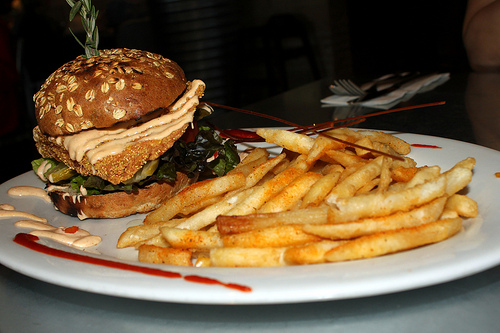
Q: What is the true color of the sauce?
A: Red.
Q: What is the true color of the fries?
A: Yellow.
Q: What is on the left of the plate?
A: A large burger.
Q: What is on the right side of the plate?
A: French fries.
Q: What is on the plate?
A: French fries and burger.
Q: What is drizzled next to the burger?
A: Mayonnaise.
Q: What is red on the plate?
A: Ketchup.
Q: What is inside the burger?
A: Meat.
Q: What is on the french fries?
A: Seasoning.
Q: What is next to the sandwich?
A: Fries.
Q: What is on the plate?
A: Food.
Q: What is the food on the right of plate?
A: Fries.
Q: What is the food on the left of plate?
A: Hamburger.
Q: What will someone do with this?
A: Eat it.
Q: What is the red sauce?
A: Ketchup.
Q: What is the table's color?
A: Gray.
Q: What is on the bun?
A: Sesame seeds.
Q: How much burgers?
A: 1.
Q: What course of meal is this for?
A: Dinner.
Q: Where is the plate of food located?
A: A restaurant.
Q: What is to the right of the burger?
A: French fries.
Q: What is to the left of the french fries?
A: A burger.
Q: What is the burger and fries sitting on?
A: A white plate.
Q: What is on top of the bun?
A: Oat seeds.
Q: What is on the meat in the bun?
A: Breading.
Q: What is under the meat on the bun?
A: Greens.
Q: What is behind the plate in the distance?
A: Fork and knife.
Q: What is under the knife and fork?
A: Napkin.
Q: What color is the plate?
A: White.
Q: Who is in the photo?
A: Nobody.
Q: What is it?
A: Food.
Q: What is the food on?
A: A plate.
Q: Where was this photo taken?
A: At a restaurant.